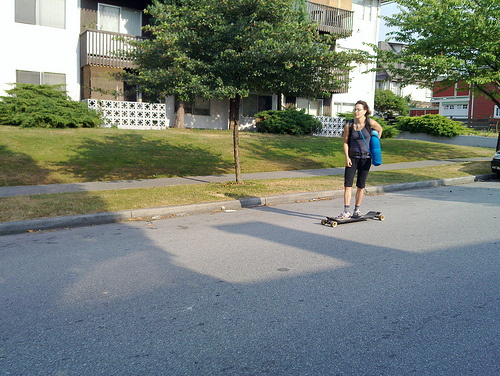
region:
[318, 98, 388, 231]
woman on black skateboard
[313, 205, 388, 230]
black skateboard with brown wheels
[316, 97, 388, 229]
blue yoga bag strapped over shoulder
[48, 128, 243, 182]
shadow of tree on grass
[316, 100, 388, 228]
woman in black capri pants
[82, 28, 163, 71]
brown railing with vertical slats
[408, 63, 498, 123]
red building with white garage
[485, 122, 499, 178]
car parked at curb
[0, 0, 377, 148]
white multi-story building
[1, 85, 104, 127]
green bush in front of window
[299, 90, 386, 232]
Woman on skatboard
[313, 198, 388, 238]
Black and white skateboard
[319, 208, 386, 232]
White wheels on skateboard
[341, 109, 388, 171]
Blue bag on woman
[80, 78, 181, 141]
white decorative fence in front of building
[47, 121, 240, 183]
Shadow of tree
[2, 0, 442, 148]
White building in the background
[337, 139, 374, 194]
Woman in black capris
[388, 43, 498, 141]
Red building in the distance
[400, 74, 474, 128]
White trim on building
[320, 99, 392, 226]
Woman on a skateboard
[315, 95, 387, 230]
Woman is on a skateboard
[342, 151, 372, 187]
Woman wearing shorts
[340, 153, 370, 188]
Woman is wearing shorts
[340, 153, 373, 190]
Woman wearing black shorts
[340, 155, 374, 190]
Woman is wearing black shorts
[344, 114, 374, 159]
Woman wearing a shirt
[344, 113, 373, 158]
Woman wearing a gray shirt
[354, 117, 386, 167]
Woman carrying a yoga mat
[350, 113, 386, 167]
Woman holding a yoga mat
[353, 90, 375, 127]
Person has brown hair.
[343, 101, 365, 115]
Glasses on person's face.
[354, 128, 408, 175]
Person carrying blue yoga mat.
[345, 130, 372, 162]
Person wearing gray shirt.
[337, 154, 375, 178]
Person wearing black shorts.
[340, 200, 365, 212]
Person wearing gray socks.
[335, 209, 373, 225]
Person standing on skateboard.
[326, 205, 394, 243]
Tan wheels on skateboard.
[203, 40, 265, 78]
Green leaves on tree.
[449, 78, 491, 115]
Red building in distance.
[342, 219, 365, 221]
A skate board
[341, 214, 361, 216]
Feet on a skate board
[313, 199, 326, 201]
Dry leaves on the side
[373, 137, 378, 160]
A blue roll tucked under the arm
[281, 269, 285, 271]
A black spot on the surface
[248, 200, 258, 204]
Shadow of skater on the kerb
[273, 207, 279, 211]
Shadow of skier on the road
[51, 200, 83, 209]
Shadow cast on the grass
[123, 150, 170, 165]
Shadow cast by a tree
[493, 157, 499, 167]
A car sticking out